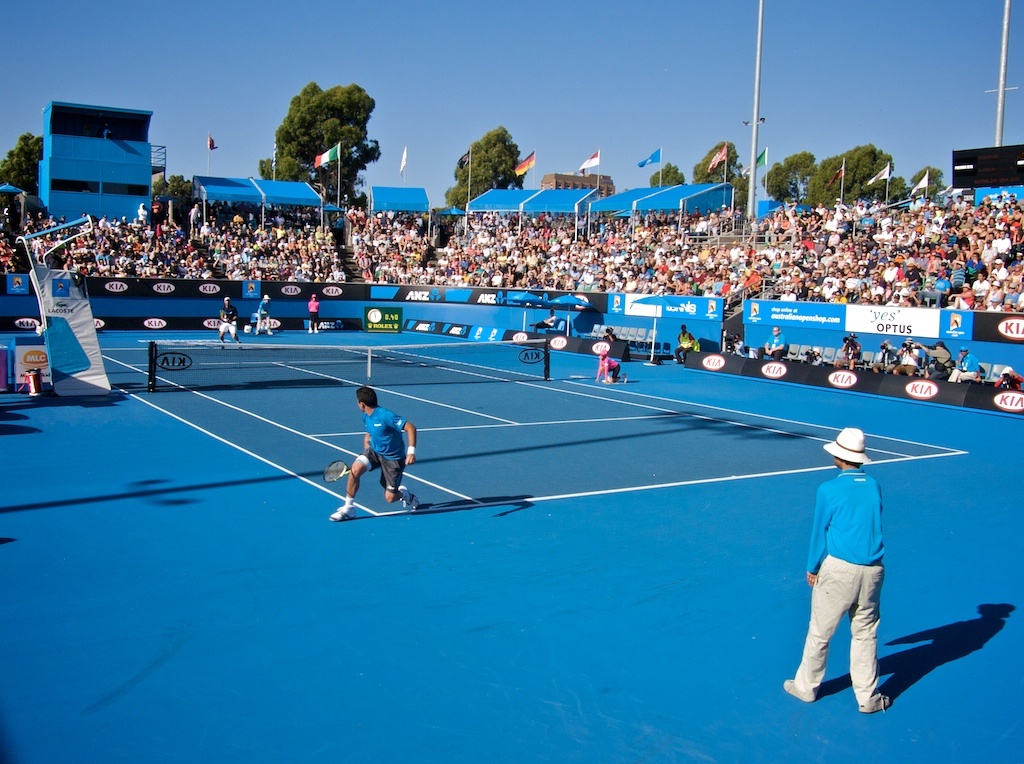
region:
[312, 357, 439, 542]
man in blue with racket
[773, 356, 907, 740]
man in blue wearing white hat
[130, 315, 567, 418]
black tennis net with kia symbol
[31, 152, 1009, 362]
spectators seated in stands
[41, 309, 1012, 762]
large blue tennis court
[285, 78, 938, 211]
green trees behind stands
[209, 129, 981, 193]
various flags on white poles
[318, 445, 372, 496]
tennis racket in hand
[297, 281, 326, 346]
person in pink on end of court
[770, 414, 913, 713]
man wearing white hat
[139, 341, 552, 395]
white and black next across the court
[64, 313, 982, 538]
blue tennis court with white lettering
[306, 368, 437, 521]
tennis player wearing blue shirt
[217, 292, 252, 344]
tennis player wearing black shirt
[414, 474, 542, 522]
shadow of the tennis player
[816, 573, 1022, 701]
shadow of the man in white hat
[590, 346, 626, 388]
person wearing pink shirt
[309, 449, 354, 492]
tennis racket tennis player is holding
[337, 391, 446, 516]
tennis player on tennis court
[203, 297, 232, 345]
tennis player on tennis court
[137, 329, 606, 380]
net stretches across tennis court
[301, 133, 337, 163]
Italian flag over tennis court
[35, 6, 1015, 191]
blue sky over tennis court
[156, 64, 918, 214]
green trees surrounding tennis court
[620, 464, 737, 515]
white lines on tennis court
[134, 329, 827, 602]
a blue tennis court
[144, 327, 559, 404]
a net on a tennis court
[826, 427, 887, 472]
a man wearing a white hat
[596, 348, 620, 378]
a person wearing a pink shirt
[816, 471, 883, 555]
a man wearing a blue shirt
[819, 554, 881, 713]
a man wearing tan pants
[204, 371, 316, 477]
white lines on a tennis court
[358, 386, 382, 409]
a man with black hair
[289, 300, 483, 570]
The man is holding a tennis racket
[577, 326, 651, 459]
The person is wearing a pink shirt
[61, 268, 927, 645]
The blue tennis court has white lines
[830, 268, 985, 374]
The sign is white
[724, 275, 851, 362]
The sign is blue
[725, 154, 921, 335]
The people are sitting on the stands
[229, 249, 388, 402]
A person in a pink shirt is standing at the back of the court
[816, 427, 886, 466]
a large white hat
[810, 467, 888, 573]
a long sleeve blue and white shirt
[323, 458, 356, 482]
a large tennis racket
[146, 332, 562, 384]
a long black and white tennis net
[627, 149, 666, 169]
a blue flag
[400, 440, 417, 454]
a white wristband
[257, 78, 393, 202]
a tall green tree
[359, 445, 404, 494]
a man's black shorts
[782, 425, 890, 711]
man is standing at the end of the court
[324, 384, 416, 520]
person is playing tennis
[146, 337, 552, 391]
tennis net is in the middle of the court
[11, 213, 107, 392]
watch booth is beside the court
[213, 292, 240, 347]
man is waiting for tennis ball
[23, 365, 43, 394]
trash can is beside the court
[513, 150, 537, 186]
flag is in the stands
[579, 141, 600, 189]
flag is above the stands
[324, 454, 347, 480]
tennis racket is in mans hand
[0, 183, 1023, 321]
crowd is in the stands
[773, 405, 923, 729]
A person is dressed in a teal sweater.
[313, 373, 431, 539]
A man is leaning down to hit a ball.